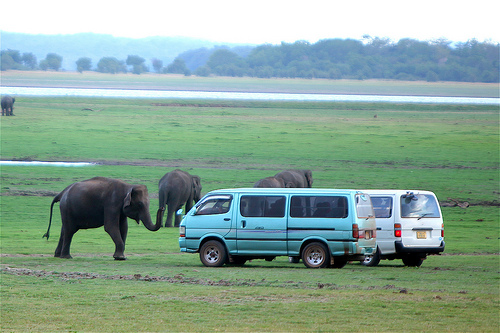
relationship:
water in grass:
[74, 144, 101, 186] [178, 289, 217, 316]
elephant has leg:
[36, 163, 154, 276] [30, 216, 135, 297]